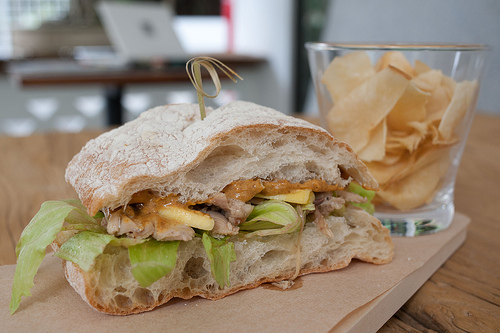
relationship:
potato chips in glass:
[326, 65, 412, 163] [304, 42, 493, 236]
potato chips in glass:
[386, 83, 431, 130] [304, 42, 493, 236]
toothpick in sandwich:
[183, 56, 244, 122] [9, 100, 397, 317]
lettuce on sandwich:
[127, 238, 180, 287] [9, 100, 397, 317]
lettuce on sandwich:
[53, 230, 150, 273] [9, 100, 397, 317]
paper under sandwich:
[2, 210, 470, 332] [9, 100, 397, 317]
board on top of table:
[333, 224, 468, 333] [0, 110, 499, 332]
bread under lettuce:
[61, 205, 395, 317] [127, 238, 180, 287]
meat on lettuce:
[106, 205, 196, 242] [127, 238, 180, 287]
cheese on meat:
[159, 205, 217, 232] [106, 205, 196, 242]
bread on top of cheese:
[63, 99, 383, 216] [159, 205, 217, 232]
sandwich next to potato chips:
[9, 100, 397, 317] [326, 65, 412, 163]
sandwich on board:
[9, 100, 397, 317] [333, 224, 468, 333]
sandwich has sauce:
[9, 100, 397, 317] [221, 179, 345, 204]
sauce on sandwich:
[110, 189, 219, 233] [9, 100, 397, 317]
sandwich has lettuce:
[9, 100, 397, 317] [53, 230, 150, 273]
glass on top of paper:
[304, 42, 493, 236] [2, 210, 470, 332]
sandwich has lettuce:
[9, 100, 397, 317] [127, 238, 180, 287]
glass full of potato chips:
[304, 42, 493, 236] [326, 65, 412, 163]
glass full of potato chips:
[304, 42, 493, 236] [386, 83, 431, 130]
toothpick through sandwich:
[183, 56, 244, 122] [9, 100, 397, 317]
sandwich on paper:
[9, 100, 397, 317] [2, 210, 470, 332]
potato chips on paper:
[326, 65, 412, 163] [2, 210, 470, 332]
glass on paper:
[304, 42, 493, 236] [2, 210, 470, 332]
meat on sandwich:
[106, 205, 196, 242] [9, 100, 397, 317]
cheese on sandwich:
[159, 205, 217, 232] [9, 100, 397, 317]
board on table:
[333, 224, 468, 333] [0, 110, 499, 332]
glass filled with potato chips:
[304, 42, 493, 236] [326, 65, 412, 163]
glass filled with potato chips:
[304, 42, 493, 236] [386, 83, 431, 130]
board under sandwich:
[333, 224, 468, 333] [9, 100, 397, 317]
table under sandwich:
[0, 110, 499, 332] [9, 100, 397, 317]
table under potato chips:
[0, 110, 499, 332] [326, 65, 412, 163]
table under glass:
[0, 110, 499, 332] [304, 42, 493, 236]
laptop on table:
[96, 2, 266, 69] [8, 60, 238, 127]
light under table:
[25, 98, 59, 122] [8, 60, 238, 127]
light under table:
[76, 94, 105, 116] [8, 60, 238, 127]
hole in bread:
[259, 248, 291, 269] [61, 205, 395, 317]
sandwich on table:
[9, 100, 397, 317] [0, 110, 499, 332]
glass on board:
[304, 42, 493, 236] [333, 224, 468, 333]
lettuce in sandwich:
[127, 238, 180, 287] [9, 100, 397, 317]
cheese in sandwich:
[159, 205, 217, 232] [9, 100, 397, 317]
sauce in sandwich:
[221, 179, 345, 204] [9, 100, 397, 317]